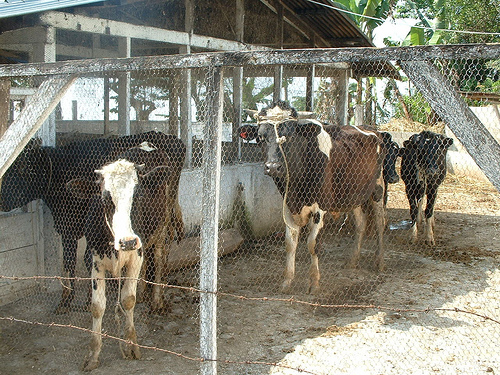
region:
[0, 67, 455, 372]
several cows in a pen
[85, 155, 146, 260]
the head of a cow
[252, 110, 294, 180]
the head of a cow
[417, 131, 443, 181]
the head of a cow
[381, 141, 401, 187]
the head of a cow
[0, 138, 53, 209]
the head of a cow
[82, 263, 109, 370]
the leg of a cow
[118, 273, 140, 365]
the leg of a cow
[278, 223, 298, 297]
the leg of a cow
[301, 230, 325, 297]
the leg of a cow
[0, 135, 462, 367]
A group of cows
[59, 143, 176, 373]
A brown and white cow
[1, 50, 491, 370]
A chicken wire fence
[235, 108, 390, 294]
A brown and white cow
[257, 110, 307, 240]
A rope hanging from a cow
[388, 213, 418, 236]
Puddle in the cattle enclosure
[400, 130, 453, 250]
A black and white cow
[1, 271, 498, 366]
Barbed wire on a fence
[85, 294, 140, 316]
Knees of a cow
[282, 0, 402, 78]
A metal barn roof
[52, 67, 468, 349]
cows in a zero grazing shed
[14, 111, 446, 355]
the cows are black and white in colour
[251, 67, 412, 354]
the cows are tied with ropes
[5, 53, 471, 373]
the fence is barbed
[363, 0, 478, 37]
the trees are green in colour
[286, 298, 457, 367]
the floor is brown in colour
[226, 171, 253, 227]
thhe wall has a green water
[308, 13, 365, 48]
the roof is made of ironsheets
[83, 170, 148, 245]
the head is white in colour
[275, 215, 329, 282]
the legs are white incolour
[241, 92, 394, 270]
this is a cow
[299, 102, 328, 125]
this is the horn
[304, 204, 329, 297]
this is the leg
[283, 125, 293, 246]
this is a rope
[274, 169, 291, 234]
the rope is white in color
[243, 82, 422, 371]
this is a fence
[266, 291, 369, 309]
this is a barbed wire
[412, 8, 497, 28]
this is a tree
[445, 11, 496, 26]
the leaves are green in color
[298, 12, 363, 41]
this is a roof